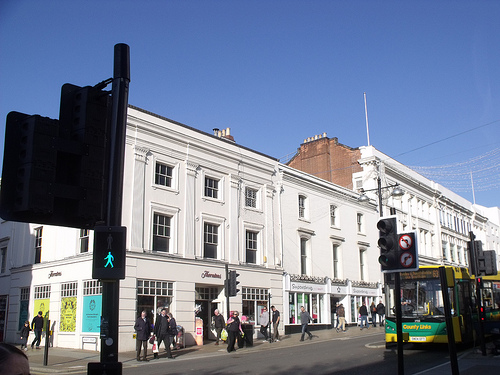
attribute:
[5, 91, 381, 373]
building — white 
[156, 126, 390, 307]
building — white 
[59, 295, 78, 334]
poster — yellow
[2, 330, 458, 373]
street — black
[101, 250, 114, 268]
man — little, green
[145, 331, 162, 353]
bag — white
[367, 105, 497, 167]
line — black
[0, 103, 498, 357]
building — brown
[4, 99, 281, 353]
building — white